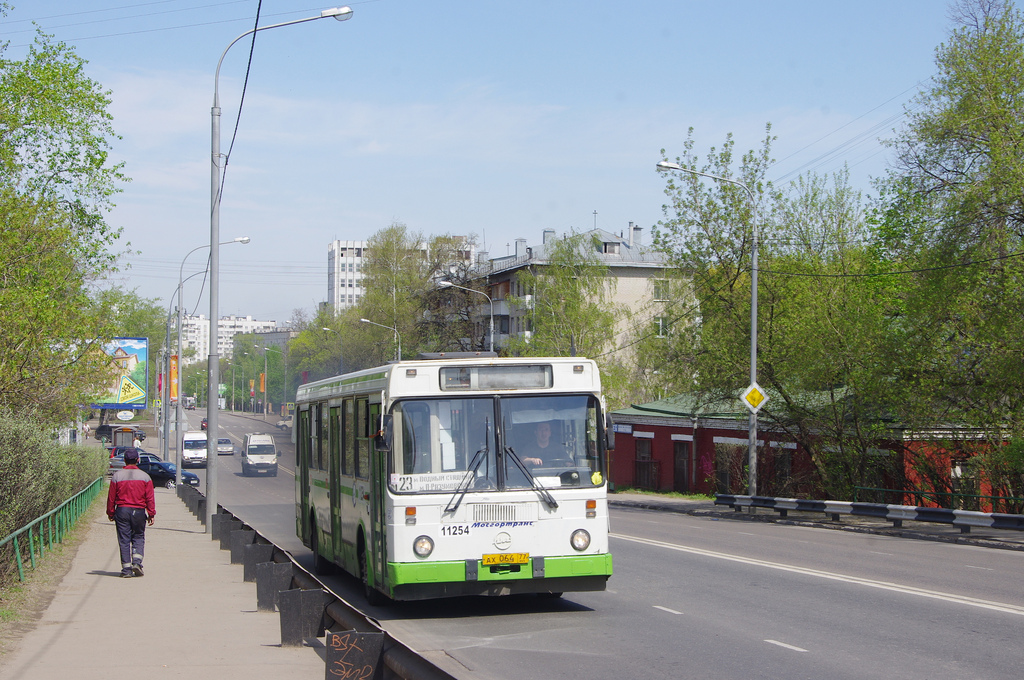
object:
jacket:
[109, 469, 155, 515]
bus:
[288, 354, 609, 605]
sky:
[5, 4, 988, 320]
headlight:
[570, 529, 589, 550]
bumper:
[383, 540, 615, 596]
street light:
[194, 1, 355, 541]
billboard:
[50, 335, 143, 409]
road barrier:
[699, 479, 1020, 552]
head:
[121, 448, 138, 466]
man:
[106, 450, 152, 574]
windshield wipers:
[444, 445, 557, 514]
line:
[644, 590, 688, 629]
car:
[216, 439, 233, 456]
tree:
[0, 6, 117, 525]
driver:
[515, 424, 573, 473]